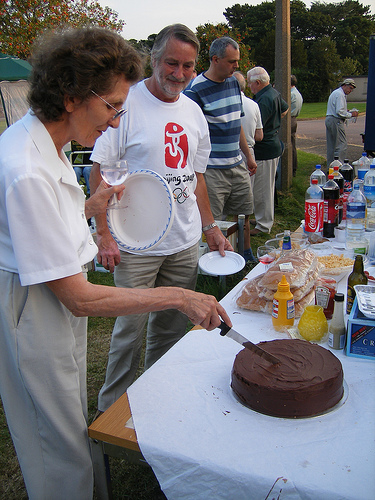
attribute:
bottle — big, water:
[342, 178, 370, 244]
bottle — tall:
[344, 183, 368, 252]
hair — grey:
[207, 37, 243, 60]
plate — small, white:
[198, 248, 243, 276]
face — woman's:
[68, 76, 131, 147]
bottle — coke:
[303, 178, 323, 242]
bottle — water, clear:
[344, 182, 367, 240]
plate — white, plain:
[198, 245, 244, 276]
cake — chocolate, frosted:
[231, 338, 348, 420]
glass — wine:
[98, 159, 128, 209]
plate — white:
[103, 167, 175, 252]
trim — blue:
[105, 167, 174, 251]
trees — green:
[223, 2, 370, 102]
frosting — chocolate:
[231, 337, 346, 420]